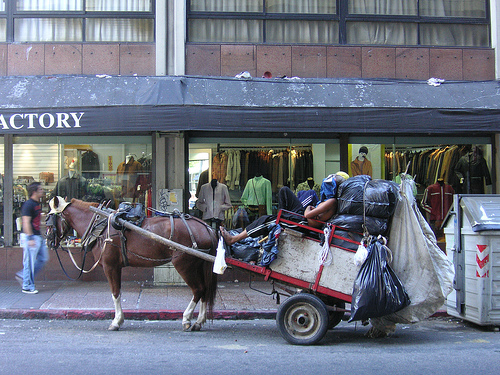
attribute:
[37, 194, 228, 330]
horse — brown, white, stationary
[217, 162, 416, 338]
wheelbarrow — red, white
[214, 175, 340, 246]
man — resting, relaxing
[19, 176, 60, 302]
man — walking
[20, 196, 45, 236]
t-shirt — blue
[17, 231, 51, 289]
jeans — blue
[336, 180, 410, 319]
bags — black, plastic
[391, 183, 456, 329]
bag — white, big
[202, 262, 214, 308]
tail — hairy, black, large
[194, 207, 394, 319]
cart — red, white, two wheeled, packed, stopped, horse drawn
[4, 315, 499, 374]
road — paved, asphalt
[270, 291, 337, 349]
wheel — rubber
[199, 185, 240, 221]
jacket — purple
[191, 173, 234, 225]
manequin — headless, black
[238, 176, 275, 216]
shirt — green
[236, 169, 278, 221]
manequin — black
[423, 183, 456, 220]
jacket — red, striped, white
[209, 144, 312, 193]
jackets — hanging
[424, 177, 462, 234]
manequin — headless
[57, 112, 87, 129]
letters — white